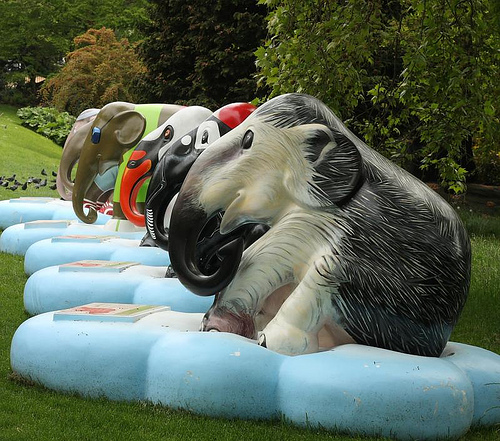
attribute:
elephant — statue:
[71, 92, 120, 235]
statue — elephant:
[160, 96, 463, 356]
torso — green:
[122, 101, 162, 188]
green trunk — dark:
[74, 145, 96, 225]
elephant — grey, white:
[166, 98, 466, 363]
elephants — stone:
[53, 57, 460, 357]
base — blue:
[7, 305, 496, 421]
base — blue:
[16, 260, 214, 310]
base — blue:
[17, 230, 172, 268]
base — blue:
[0, 220, 144, 255]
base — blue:
[2, 195, 83, 225]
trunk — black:
[174, 198, 244, 295]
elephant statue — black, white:
[174, 101, 469, 351]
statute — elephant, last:
[56, 122, 109, 211]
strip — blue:
[89, 125, 106, 143]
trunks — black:
[131, 194, 353, 343]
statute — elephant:
[158, 89, 473, 364]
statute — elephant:
[144, 103, 254, 246]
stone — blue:
[6, 302, 499, 439]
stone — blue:
[24, 258, 222, 312]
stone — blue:
[24, 232, 175, 274]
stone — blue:
[0, 217, 175, 259]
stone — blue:
[0, 194, 103, 234]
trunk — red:
[94, 67, 473, 372]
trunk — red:
[119, 142, 150, 223]